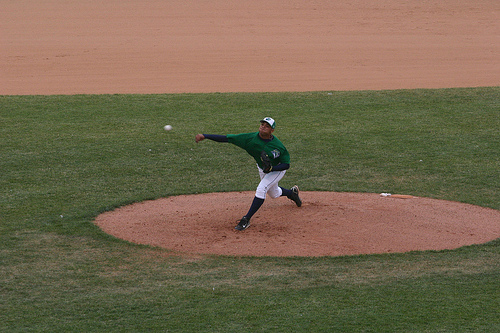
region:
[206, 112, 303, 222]
Baseball pitcher throwing a ball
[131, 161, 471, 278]
baseball pitcher's mound is dirt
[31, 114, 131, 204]
short green manicured lawn of baseball field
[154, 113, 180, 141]
baseball leaving pitcher's hand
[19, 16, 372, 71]
infield of baseball field is clay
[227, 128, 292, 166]
player is wearing a green uniform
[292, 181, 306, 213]
baseball player is wearing cleats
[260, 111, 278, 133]
baseball player is wearing a cap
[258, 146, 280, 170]
baseball player is wearing a glove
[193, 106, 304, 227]
baseball player is a pitcher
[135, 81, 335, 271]
baseball player throwing ball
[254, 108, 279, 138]
baseball player wearing hat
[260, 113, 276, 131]
baseball hat is white and green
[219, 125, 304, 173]
baseball player wearing green top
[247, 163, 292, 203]
baseball player wearing white pants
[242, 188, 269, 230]
baseball player wearing black socks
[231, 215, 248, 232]
player wearing black shoes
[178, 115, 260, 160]
player has arm extended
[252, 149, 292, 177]
player holding catches mitt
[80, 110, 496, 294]
player standing in dirt circle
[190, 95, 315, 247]
PErson in a field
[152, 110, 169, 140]
White ball in the field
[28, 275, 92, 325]
Small patch of green grass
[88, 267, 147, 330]
Small patch of green grass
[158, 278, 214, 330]
Small patch of green grass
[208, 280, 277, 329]
Small patch of green grass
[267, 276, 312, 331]
Small patch of green grass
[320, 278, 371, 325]
Small patch of green grass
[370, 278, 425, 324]
Small patch of green grass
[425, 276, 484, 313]
Small patch of green grass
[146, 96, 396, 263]
player throwing a baseball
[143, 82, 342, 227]
this is a pitcher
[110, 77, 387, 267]
the pitcher throws the ball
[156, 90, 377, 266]
the pitcher is on the mound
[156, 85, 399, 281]
the player is wearing green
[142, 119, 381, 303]
the team colors are green and white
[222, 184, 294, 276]
the socks are black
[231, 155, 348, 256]
the pants are white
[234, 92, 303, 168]
the hat is green and white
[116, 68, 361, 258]
the ball is in motion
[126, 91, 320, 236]
a professional baseball player pitching the ball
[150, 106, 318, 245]
a pitcher throwing the ball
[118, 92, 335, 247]
a man pitching the ball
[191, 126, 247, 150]
the arm of a man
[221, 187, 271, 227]
the leg of a man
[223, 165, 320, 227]
the legs of a man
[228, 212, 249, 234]
the foot of a man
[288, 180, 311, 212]
the foot of a man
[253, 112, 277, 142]
a man wearing a baseball cap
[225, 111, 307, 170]
a man wearing a green jersey